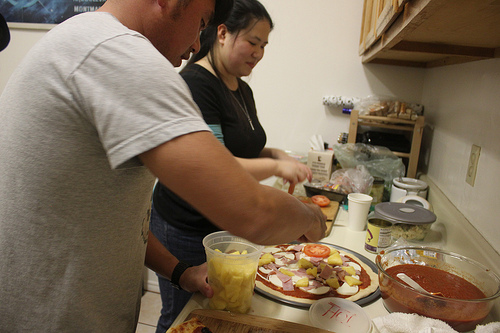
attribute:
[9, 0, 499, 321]
woman — standing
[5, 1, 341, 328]
man — standing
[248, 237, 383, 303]
pizza — uncooked, homemade, ucooked, round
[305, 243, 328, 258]
slice — tomato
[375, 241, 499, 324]
bowl — glass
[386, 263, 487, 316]
sauce — red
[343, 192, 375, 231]
cup — white, styrofoam, plastic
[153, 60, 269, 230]
top — black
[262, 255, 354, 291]
ham — sliced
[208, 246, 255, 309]
cheese — cut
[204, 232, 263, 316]
container — platic, plastic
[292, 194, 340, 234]
cutting board — wood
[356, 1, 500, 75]
cabinets — wooden, kitchen cabinets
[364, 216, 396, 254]
can — opened, aluminum, metal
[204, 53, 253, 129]
necklace — silver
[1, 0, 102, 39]
picture — hanging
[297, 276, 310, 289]
piece — food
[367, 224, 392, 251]
label — yellow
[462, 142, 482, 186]
switch plate — white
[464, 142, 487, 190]
outlet — electrical, electric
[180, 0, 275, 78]
hair — black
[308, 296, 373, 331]
lid — plastic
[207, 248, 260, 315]
food — yellow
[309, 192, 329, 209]
slice — tomato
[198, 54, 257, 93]
neck — woman's